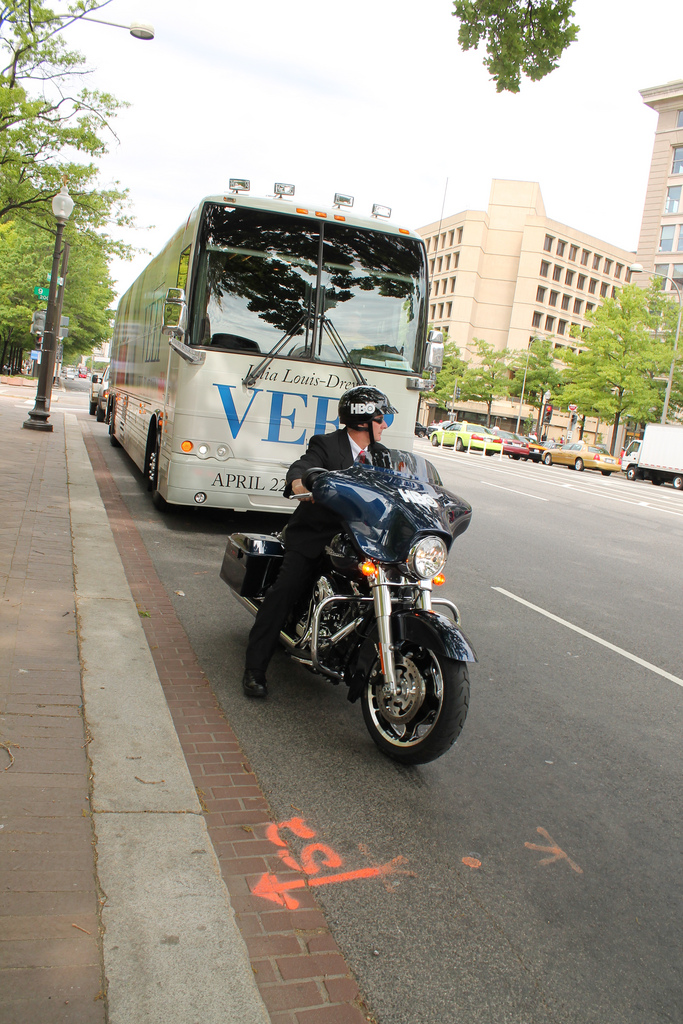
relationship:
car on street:
[428, 418, 505, 458] [432, 434, 675, 789]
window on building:
[539, 233, 555, 254] [412, 176, 642, 458]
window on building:
[556, 238, 568, 257] [412, 176, 642, 458]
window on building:
[540, 259, 550, 277] [412, 176, 642, 458]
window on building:
[533, 284, 546, 303] [412, 176, 642, 458]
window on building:
[604, 256, 613, 276] [412, 176, 642, 458]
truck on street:
[623, 411, 682, 500] [445, 445, 628, 619]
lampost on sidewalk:
[19, 181, 78, 438] [5, 366, 281, 1013]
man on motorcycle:
[228, 376, 422, 711] [216, 474, 539, 761]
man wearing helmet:
[228, 377, 422, 713] [335, 384, 391, 423]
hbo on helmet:
[347, 398, 377, 417] [338, 386, 398, 426]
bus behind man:
[102, 170, 440, 535] [295, 389, 404, 481]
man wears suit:
[228, 377, 422, 713] [244, 427, 397, 660]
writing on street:
[234, 751, 610, 925] [61, 409, 676, 1019]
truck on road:
[623, 411, 682, 499] [387, 433, 681, 704]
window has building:
[531, 307, 543, 327] [422, 167, 633, 460]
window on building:
[539, 233, 555, 253] [422, 167, 633, 460]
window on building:
[590, 252, 602, 269] [422, 167, 633, 460]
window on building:
[453, 226, 464, 244] [422, 167, 633, 460]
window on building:
[573, 298, 583, 314] [422, 167, 633, 460]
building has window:
[412, 176, 642, 458] [559, 292, 575, 307]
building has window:
[412, 176, 642, 458] [569, 267, 591, 295]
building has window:
[412, 176, 642, 458] [561, 266, 576, 293]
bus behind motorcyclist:
[102, 172, 440, 511] [214, 384, 493, 768]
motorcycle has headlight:
[210, 409, 521, 771] [399, 533, 451, 581]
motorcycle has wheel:
[215, 447, 482, 770] [342, 616, 474, 768]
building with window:
[412, 176, 642, 458] [540, 258, 551, 275]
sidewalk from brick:
[2, 417, 185, 1003] [133, 564, 191, 689]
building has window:
[412, 176, 642, 458] [539, 233, 555, 253]